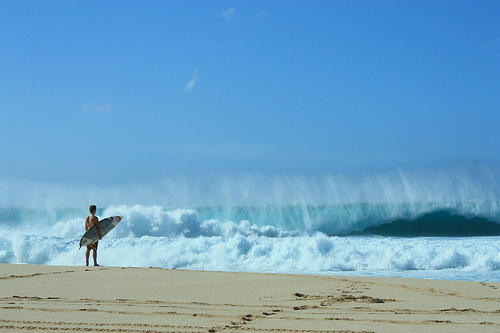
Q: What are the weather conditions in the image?
A: It is clear.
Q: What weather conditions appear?
A: It is clear.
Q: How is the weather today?
A: It is clear.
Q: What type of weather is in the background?
A: It is clear.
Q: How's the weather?
A: It is clear.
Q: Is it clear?
A: Yes, it is clear.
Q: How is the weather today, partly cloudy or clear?
A: It is clear.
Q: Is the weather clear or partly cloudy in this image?
A: It is clear.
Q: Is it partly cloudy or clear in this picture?
A: It is clear.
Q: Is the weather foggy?
A: No, it is clear.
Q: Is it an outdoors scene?
A: Yes, it is outdoors.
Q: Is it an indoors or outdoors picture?
A: It is outdoors.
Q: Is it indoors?
A: No, it is outdoors.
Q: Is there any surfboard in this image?
A: Yes, there is a surfboard.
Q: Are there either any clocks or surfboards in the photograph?
A: Yes, there is a surfboard.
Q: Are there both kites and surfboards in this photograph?
A: No, there is a surfboard but no kites.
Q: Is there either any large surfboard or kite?
A: Yes, there is a large surfboard.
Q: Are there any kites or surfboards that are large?
A: Yes, the surfboard is large.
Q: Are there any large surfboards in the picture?
A: Yes, there is a large surfboard.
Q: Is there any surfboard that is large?
A: Yes, there is a surfboard that is large.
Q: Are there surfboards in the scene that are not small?
A: Yes, there is a large surfboard.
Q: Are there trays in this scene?
A: No, there are no trays.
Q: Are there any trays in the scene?
A: No, there are no trays.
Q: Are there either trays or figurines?
A: No, there are no trays or figurines.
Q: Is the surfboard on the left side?
A: Yes, the surfboard is on the left of the image.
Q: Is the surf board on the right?
A: No, the surf board is on the left of the image.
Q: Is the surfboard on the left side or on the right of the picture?
A: The surfboard is on the left of the image.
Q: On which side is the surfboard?
A: The surfboard is on the left of the image.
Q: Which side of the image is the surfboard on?
A: The surfboard is on the left of the image.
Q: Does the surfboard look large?
A: Yes, the surfboard is large.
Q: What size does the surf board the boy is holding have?
A: The surfboard has large size.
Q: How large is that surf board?
A: The surf board is large.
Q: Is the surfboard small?
A: No, the surfboard is large.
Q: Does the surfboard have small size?
A: No, the surfboard is large.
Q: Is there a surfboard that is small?
A: No, there is a surfboard but it is large.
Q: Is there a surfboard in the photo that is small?
A: No, there is a surfboard but it is large.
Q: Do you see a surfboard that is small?
A: No, there is a surfboard but it is large.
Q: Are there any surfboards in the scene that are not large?
A: No, there is a surfboard but it is large.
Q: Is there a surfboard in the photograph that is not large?
A: No, there is a surfboard but it is large.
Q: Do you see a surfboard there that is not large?
A: No, there is a surfboard but it is large.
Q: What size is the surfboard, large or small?
A: The surfboard is large.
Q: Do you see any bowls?
A: No, there are no bowls.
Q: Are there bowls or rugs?
A: No, there are no bowls or rugs.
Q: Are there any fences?
A: No, there are no fences.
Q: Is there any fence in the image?
A: No, there are no fences.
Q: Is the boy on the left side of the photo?
A: Yes, the boy is on the left of the image.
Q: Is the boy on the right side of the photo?
A: No, the boy is on the left of the image.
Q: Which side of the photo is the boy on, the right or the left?
A: The boy is on the left of the image.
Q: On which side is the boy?
A: The boy is on the left of the image.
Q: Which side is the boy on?
A: The boy is on the left of the image.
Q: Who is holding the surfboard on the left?
A: The boy is holding the surf board.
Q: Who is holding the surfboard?
A: The boy is holding the surf board.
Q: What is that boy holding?
A: The boy is holding the surfboard.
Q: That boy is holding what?
A: The boy is holding the surfboard.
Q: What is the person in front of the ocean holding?
A: The boy is holding the surfboard.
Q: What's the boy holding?
A: The boy is holding the surfboard.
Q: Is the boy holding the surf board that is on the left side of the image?
A: Yes, the boy is holding the surf board.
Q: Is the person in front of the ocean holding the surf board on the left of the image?
A: Yes, the boy is holding the surf board.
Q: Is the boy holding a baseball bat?
A: No, the boy is holding the surf board.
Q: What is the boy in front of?
A: The boy is in front of the ocean.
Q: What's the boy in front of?
A: The boy is in front of the ocean.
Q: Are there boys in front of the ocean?
A: Yes, there is a boy in front of the ocean.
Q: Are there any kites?
A: No, there are no kites.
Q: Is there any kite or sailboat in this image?
A: No, there are no kites or sailboats.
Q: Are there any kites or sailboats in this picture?
A: No, there are no kites or sailboats.